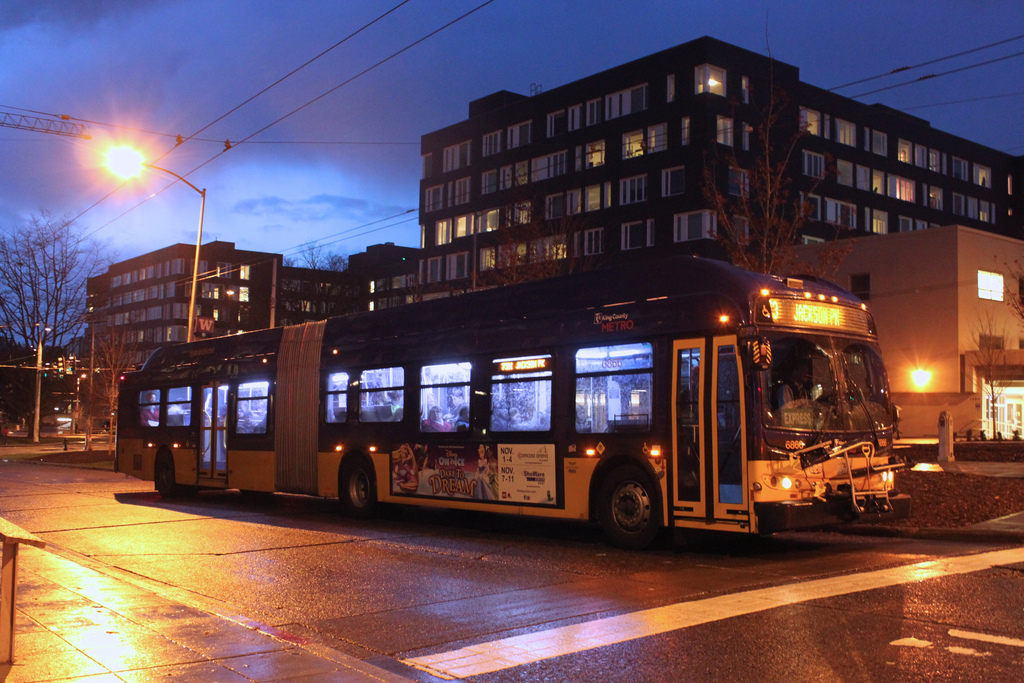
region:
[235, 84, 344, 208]
blue and grey sky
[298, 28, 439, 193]
grey and thick clouds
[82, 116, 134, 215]
yellow light is shining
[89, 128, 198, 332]
light on grey pole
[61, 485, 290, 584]
road is dark grey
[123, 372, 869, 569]
bus is stopped on road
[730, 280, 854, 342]
orange LCD on bus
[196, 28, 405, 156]
power lines are black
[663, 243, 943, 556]
front of the bus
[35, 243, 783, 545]
side of the bus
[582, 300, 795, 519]
door to the bus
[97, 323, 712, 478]
light inside the bus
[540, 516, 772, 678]
white line on ground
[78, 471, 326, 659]
light hitting the ground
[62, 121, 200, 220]
light above the ground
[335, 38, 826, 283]
building in the distance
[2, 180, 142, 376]
tree in the distance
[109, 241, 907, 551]
Bus on the road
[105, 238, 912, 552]
Bus on the street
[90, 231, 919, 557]
Bus is on the street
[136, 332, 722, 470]
Lights on the bus turned on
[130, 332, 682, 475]
Lights on the bus are turned on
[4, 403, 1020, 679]
Ground is wet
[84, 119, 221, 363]
Street light lamp is on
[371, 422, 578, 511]
Advertisement on side of the bus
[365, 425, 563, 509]
Advertisement is on side of the bus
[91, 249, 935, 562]
the bus is long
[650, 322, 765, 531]
the front door of a bus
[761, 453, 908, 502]
headlights of a bus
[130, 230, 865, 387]
the roof is color black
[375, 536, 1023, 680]
the line is white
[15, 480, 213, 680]
yellow light on the road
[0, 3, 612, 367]
wires above a bus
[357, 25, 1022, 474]
a building behind a bus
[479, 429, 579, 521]
white sign on the bus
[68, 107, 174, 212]
bright street light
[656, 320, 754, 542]
closed door on bus front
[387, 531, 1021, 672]
white line on street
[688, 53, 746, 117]
light in window of building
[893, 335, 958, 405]
light hanging on building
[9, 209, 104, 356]
tree to left of buildings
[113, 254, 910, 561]
a public service bus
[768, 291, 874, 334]
an electronic bus destination sign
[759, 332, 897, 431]
a bus front windshield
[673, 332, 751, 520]
a bus entry door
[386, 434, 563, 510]
a bus advertising billboard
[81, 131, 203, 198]
an overhead street light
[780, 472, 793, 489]
a bus front headlight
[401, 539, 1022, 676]
a painted white street line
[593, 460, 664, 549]
a black bus tire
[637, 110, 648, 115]
a window on the building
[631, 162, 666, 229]
a window on the building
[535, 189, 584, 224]
a window on the building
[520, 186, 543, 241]
a window on the building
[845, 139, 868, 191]
a window on the building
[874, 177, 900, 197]
a window on the building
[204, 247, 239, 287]
a window on the building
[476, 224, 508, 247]
a window on the building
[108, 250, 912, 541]
very long black and yellow bus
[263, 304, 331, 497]
object attaching two parts of a bus